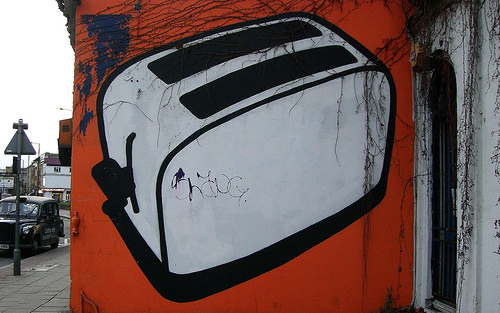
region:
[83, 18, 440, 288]
This is street art.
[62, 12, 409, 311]
This painting is on a wall.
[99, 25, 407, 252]
This is a toaster.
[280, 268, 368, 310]
the background is orange.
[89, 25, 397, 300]
The toaster is black and white.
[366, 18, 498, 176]
There are vines growing on the wall.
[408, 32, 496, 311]
This is a window.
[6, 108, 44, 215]
this is a street sign.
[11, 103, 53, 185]
The sign is shaped like a triangle.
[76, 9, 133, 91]
Part of the wall is cracking and blue.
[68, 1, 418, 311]
reddish orange colored wall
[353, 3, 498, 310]
vines are growing up and over the walls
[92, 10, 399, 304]
toaster painted on the wall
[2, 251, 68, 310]
gray sidewalk in front of the building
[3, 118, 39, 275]
triangular street sign on a pole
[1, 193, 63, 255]
old car sitting on the street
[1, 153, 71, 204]
buildings down the street of the city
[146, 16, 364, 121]
slots for bread in the toaster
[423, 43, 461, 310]
arched window in the wall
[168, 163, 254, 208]
writing on the toaster on the wall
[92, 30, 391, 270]
A white and black toaster painting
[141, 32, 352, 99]
The openings of the painted toaster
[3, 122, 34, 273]
A sign by the wall painting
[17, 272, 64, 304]
The sidewalk by the sign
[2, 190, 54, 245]
A car on the road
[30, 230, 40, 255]
The front tire of the car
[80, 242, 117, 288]
The wall is painted orange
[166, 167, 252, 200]
A signature on the painting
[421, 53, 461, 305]
An arched window by the painting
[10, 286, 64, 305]
Cracks in the sidewalk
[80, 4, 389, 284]
A toaster on the sign.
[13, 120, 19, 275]
Grey signpost next to street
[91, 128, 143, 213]
Toaster handle half-way up.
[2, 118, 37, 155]
Traffic sign on signpost.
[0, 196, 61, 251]
Dark color car behind signpost.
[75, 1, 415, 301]
The toaster is painted on the side of a building.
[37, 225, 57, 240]
The car has lettering on the side.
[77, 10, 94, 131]
Some blue color appears with the background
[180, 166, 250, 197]
Initials KWG on painting of toaster.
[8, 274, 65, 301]
The sidewalk has small squares.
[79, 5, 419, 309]
large toaster clip art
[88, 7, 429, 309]
large toaster painted on wall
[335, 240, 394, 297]
red paint on wall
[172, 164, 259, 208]
graffiti letters on wall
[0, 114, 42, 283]
triangle street sign on sidewalk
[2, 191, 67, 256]
black classic car parked near sidewalk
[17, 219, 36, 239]
round white head lights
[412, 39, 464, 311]
curved old thick window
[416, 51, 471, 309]
dark steel rails on window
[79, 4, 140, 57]
plant vines on wall